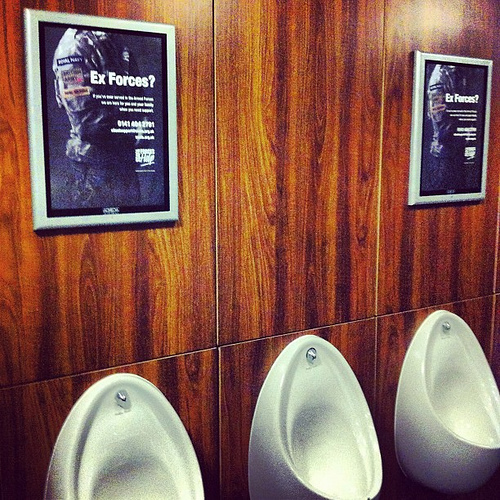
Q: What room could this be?
A: It is a bathroom.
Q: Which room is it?
A: It is a bathroom.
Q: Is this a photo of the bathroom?
A: Yes, it is showing the bathroom.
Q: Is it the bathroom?
A: Yes, it is the bathroom.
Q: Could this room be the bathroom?
A: Yes, it is the bathroom.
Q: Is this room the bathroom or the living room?
A: It is the bathroom.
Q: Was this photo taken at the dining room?
A: No, the picture was taken in the bathroom.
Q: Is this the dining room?
A: No, it is the bathroom.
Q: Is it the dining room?
A: No, it is the bathroom.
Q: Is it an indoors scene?
A: Yes, it is indoors.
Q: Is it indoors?
A: Yes, it is indoors.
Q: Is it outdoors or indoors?
A: It is indoors.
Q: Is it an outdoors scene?
A: No, it is indoors.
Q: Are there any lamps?
A: No, there are no lamps.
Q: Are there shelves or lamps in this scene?
A: No, there are no lamps or shelves.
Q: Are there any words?
A: Yes, there are words.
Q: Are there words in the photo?
A: Yes, there are words.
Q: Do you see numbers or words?
A: Yes, there are words.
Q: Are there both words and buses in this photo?
A: No, there are words but no buses.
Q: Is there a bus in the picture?
A: No, there are no buses.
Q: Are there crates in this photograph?
A: No, there are no crates.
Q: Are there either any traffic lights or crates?
A: No, there are no crates or traffic lights.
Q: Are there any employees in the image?
A: No, there are no employees.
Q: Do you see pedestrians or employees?
A: No, there are no employees or pedestrians.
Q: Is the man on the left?
A: Yes, the man is on the left of the image.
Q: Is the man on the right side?
A: No, the man is on the left of the image.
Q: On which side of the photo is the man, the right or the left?
A: The man is on the left of the image.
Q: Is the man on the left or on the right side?
A: The man is on the left of the image.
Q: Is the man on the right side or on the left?
A: The man is on the left of the image.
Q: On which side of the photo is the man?
A: The man is on the left of the image.